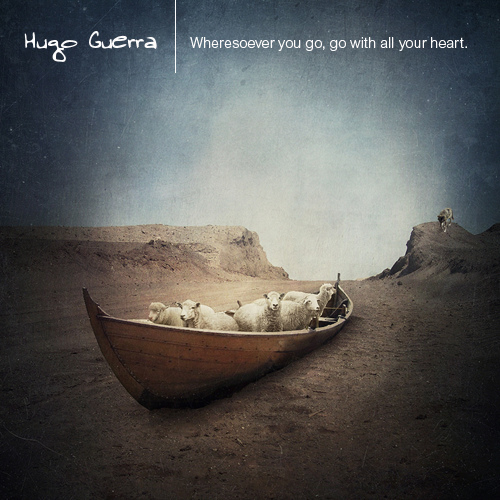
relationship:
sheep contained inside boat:
[148, 300, 184, 331] [66, 271, 402, 416]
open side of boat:
[304, 280, 356, 320] [81, 271, 354, 414]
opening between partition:
[249, 224, 414, 280] [4, 227, 498, 495]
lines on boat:
[106, 331, 286, 356] [81, 271, 354, 414]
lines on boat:
[116, 344, 247, 370] [81, 271, 354, 414]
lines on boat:
[125, 357, 222, 379] [81, 271, 354, 414]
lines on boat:
[138, 376, 210, 391] [81, 271, 354, 414]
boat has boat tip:
[92, 280, 358, 397] [48, 267, 138, 381]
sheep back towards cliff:
[148, 300, 184, 331] [385, 210, 490, 280]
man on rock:
[439, 205, 453, 231] [402, 218, 495, 274]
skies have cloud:
[262, 150, 433, 212] [113, 77, 465, 253]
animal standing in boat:
[233, 289, 282, 333] [81, 271, 354, 414]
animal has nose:
[237, 289, 282, 333] [272, 303, 279, 308]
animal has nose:
[233, 289, 282, 333] [181, 312, 188, 322]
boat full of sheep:
[81, 271, 354, 414] [145, 281, 340, 334]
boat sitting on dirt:
[81, 271, 354, 414] [325, 362, 478, 460]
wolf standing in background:
[434, 196, 461, 238] [334, 163, 484, 284]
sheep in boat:
[174, 294, 240, 333] [83, 261, 354, 426]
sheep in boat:
[146, 294, 190, 328] [83, 261, 354, 426]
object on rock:
[434, 206, 455, 232] [373, 220, 464, 263]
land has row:
[48, 217, 217, 289] [70, 237, 219, 285]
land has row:
[48, 217, 217, 289] [125, 218, 257, 246]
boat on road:
[81, 271, 354, 414] [158, 247, 340, 281]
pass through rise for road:
[244, 227, 424, 287] [8, 175, 468, 497]